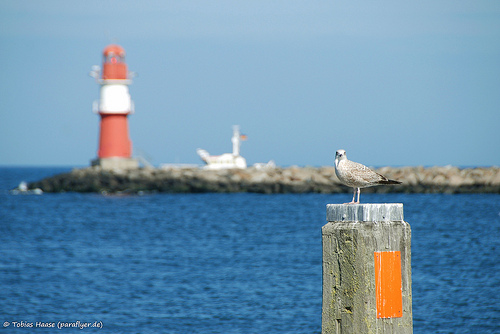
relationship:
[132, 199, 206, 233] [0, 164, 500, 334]
wave in lagoon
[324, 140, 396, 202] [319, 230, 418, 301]
seabird on pole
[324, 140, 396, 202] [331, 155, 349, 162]
seabird has beak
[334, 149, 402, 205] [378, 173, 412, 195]
seagull has tail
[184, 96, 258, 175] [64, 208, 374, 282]
ship on ocean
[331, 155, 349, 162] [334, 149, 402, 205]
beak on seagull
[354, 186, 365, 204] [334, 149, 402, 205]
leg on seagull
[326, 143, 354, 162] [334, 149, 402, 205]
head on seagull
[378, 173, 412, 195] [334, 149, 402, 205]
tail of seagull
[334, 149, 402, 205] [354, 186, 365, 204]
seagull has leg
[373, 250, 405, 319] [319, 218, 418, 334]
sign on side of pole